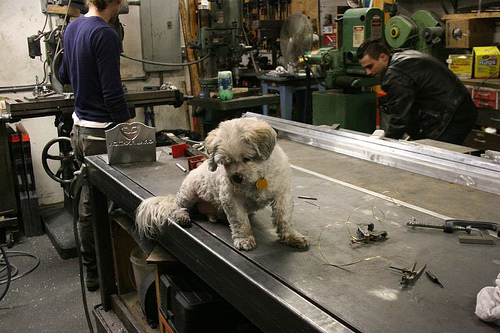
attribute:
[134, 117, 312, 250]
dog — white, sitting, small, looking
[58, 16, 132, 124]
shirt — blue, purple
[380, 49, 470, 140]
jacket — black, leather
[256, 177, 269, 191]
tag — yellow, gold, round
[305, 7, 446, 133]
equipment — green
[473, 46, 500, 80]
box — yellow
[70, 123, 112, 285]
pants — gray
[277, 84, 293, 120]
leg — blue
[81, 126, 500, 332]
table — metal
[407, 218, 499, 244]
vice grip — metal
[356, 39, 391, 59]
hair — short, black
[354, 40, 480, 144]
man — leaning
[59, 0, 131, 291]
person — facing right, standing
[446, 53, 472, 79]
box — square, yellow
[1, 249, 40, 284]
cord — grey, on floor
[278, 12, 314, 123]
house fan — electric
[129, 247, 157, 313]
bucket — white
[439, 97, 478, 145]
pants — black